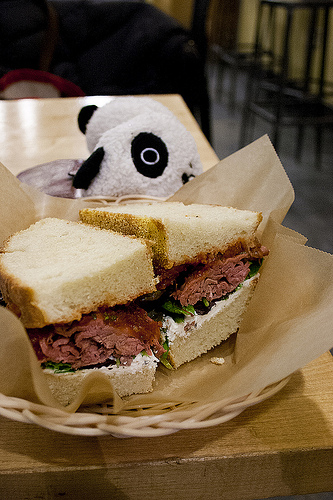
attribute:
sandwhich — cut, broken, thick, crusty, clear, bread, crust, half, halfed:
[12, 220, 261, 382]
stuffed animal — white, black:
[75, 95, 186, 188]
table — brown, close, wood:
[15, 100, 44, 129]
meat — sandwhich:
[178, 252, 255, 320]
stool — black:
[259, 6, 328, 160]